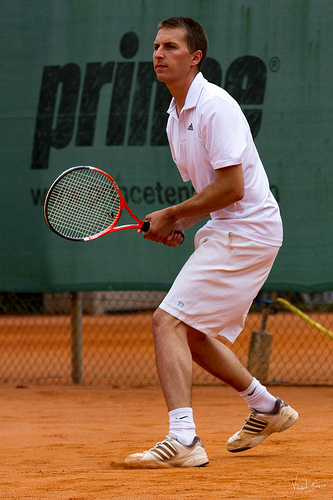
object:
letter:
[223, 55, 267, 143]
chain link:
[0, 287, 332, 389]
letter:
[75, 61, 114, 147]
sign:
[0, 0, 333, 294]